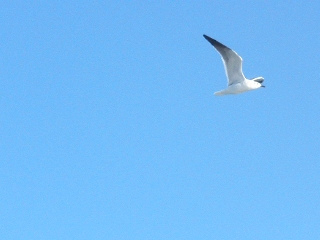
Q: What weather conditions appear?
A: It is cloudless.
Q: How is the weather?
A: It is cloudless.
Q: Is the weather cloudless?
A: Yes, it is cloudless.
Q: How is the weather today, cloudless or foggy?
A: It is cloudless.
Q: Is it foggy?
A: No, it is cloudless.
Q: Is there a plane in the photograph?
A: No, there are no airplanes.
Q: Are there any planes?
A: No, there are no planes.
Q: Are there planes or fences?
A: No, there are no planes or fences.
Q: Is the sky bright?
A: Yes, the sky is bright.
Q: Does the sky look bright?
A: Yes, the sky is bright.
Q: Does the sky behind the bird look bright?
A: Yes, the sky is bright.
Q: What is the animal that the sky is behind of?
A: The animal is a bird.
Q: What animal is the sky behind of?
A: The sky is behind the bird.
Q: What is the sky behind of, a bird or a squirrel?
A: The sky is behind a bird.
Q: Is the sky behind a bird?
A: Yes, the sky is behind a bird.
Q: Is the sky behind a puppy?
A: No, the sky is behind a bird.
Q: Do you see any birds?
A: Yes, there is a bird.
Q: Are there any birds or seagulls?
A: Yes, there is a bird.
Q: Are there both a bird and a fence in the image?
A: No, there is a bird but no fences.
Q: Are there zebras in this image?
A: No, there are no zebras.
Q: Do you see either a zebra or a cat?
A: No, there are no zebras or cats.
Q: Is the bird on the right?
A: Yes, the bird is on the right of the image.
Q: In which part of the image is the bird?
A: The bird is on the right of the image.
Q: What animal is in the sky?
A: The bird is in the sky.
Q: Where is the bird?
A: The bird is in the sky.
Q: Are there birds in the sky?
A: Yes, there is a bird in the sky.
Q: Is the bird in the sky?
A: Yes, the bird is in the sky.